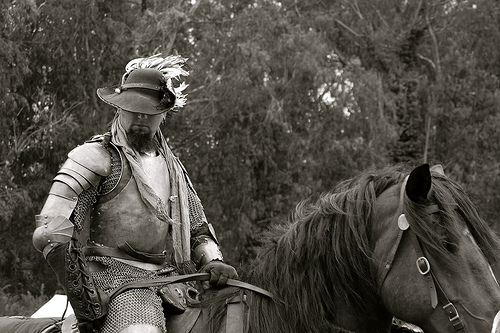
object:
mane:
[237, 162, 405, 332]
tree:
[7, 10, 498, 266]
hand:
[203, 252, 250, 284]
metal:
[180, 218, 220, 250]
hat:
[91, 51, 195, 120]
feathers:
[124, 52, 190, 88]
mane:
[188, 160, 498, 332]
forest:
[199, 15, 487, 162]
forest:
[246, 47, 408, 156]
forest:
[404, 89, 416, 116]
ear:
[403, 162, 433, 207]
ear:
[405, 163, 452, 184]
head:
[388, 159, 497, 324]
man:
[31, 53, 238, 329]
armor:
[33, 139, 228, 329]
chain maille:
[59, 139, 169, 331]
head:
[84, 57, 192, 156]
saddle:
[33, 264, 243, 331]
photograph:
[3, 3, 499, 331]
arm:
[31, 155, 106, 331]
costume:
[32, 120, 224, 330]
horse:
[6, 161, 496, 330]